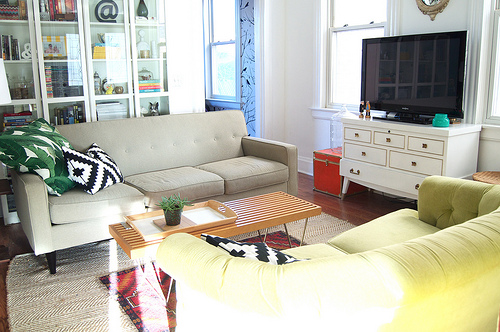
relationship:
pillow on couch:
[62, 141, 124, 194] [10, 110, 297, 275]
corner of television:
[438, 26, 469, 61] [349, 28, 470, 126]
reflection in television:
[372, 44, 452, 103] [357, 26, 469, 125]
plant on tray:
[154, 189, 184, 229] [126, 199, 237, 242]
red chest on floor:
[308, 144, 340, 191] [296, 168, 321, 199]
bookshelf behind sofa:
[1, 0, 177, 222] [35, 115, 305, 194]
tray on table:
[124, 200, 238, 242] [72, 151, 334, 285]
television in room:
[357, 26, 469, 125] [3, 0, 496, 330]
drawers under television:
[339, 110, 482, 218] [325, 20, 499, 127]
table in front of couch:
[113, 148, 341, 293] [128, 187, 498, 304]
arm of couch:
[242, 134, 295, 169] [10, 111, 304, 244]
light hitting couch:
[162, 244, 405, 330] [156, 172, 499, 329]